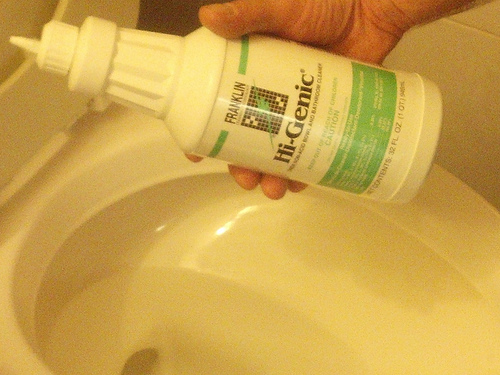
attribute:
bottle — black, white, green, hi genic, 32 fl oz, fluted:
[7, 15, 444, 208]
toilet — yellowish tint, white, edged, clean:
[1, 1, 497, 374]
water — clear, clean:
[45, 264, 363, 374]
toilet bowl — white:
[1, 96, 498, 374]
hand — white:
[197, 1, 488, 196]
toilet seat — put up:
[1, 1, 145, 187]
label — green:
[204, 32, 412, 205]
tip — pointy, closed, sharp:
[9, 31, 44, 59]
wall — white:
[139, 1, 499, 216]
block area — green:
[321, 57, 400, 195]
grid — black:
[239, 85, 288, 133]